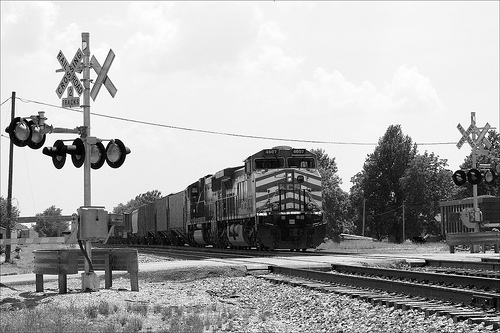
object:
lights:
[286, 169, 293, 183]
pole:
[82, 30, 89, 260]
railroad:
[263, 256, 499, 333]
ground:
[0, 236, 499, 333]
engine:
[185, 146, 328, 252]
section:
[4, 32, 138, 292]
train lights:
[4, 115, 127, 170]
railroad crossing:
[0, 30, 499, 267]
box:
[76, 206, 109, 242]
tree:
[308, 124, 500, 244]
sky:
[0, 1, 499, 230]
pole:
[4, 91, 16, 262]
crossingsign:
[456, 120, 497, 154]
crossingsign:
[54, 47, 117, 101]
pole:
[470, 112, 479, 253]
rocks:
[212, 269, 290, 305]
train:
[108, 145, 327, 249]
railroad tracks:
[104, 240, 500, 325]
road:
[0, 252, 498, 286]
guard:
[258, 224, 327, 249]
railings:
[214, 195, 240, 221]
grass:
[0, 301, 218, 333]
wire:
[0, 96, 469, 146]